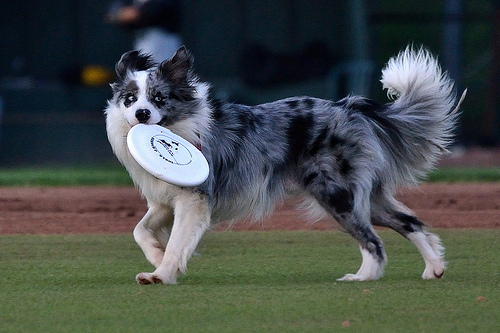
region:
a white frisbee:
[126, 122, 211, 188]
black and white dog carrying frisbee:
[99, 40, 466, 288]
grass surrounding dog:
[0, 228, 499, 331]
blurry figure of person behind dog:
[106, 0, 186, 67]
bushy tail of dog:
[361, 40, 469, 190]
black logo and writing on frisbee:
[148, 130, 195, 169]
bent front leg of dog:
[130, 203, 172, 265]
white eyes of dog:
[124, 93, 164, 105]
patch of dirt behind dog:
[0, 183, 499, 234]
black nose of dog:
[134, 107, 151, 122]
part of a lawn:
[316, 265, 343, 295]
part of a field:
[78, 225, 89, 234]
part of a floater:
[169, 158, 178, 178]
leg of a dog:
[364, 259, 383, 271]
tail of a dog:
[408, 145, 413, 170]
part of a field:
[272, 313, 282, 325]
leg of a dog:
[359, 268, 365, 272]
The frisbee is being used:
[127, 122, 208, 188]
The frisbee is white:
[125, 122, 210, 184]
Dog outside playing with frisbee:
[106, 42, 451, 282]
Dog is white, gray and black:
[105, 45, 465, 280]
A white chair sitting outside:
[322, 60, 377, 97]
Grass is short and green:
[0, 227, 495, 327]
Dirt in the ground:
[2, 182, 497, 232]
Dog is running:
[105, 50, 460, 280]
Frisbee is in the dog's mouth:
[125, 120, 207, 181]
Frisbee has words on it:
[125, 125, 208, 185]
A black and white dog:
[103, 45, 470, 285]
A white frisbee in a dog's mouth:
[125, 118, 210, 188]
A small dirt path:
[0, 182, 495, 229]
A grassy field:
[2, 165, 497, 182]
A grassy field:
[1, 230, 493, 327]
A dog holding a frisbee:
[101, 45, 461, 285]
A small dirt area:
[435, 145, 495, 165]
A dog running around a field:
[105, 40, 465, 290]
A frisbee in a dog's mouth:
[125, 120, 205, 185]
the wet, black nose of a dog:
[134, 107, 151, 122]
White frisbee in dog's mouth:
[126, 120, 221, 190]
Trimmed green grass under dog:
[3, 226, 498, 331]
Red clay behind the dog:
[0, 189, 491, 231]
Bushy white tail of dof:
[351, 44, 485, 178]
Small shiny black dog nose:
[130, 106, 152, 126]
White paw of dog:
[135, 208, 164, 256]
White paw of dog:
[146, 228, 219, 332]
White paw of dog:
[345, 243, 404, 293]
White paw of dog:
[400, 218, 473, 285]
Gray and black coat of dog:
[212, 94, 397, 222]